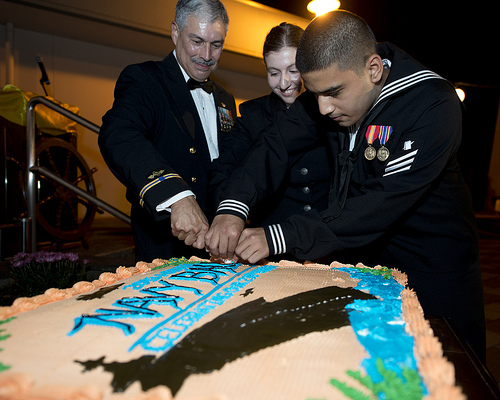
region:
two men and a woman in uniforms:
[98, 1, 488, 398]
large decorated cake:
[0, 251, 473, 398]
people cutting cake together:
[0, 1, 486, 398]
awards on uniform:
[362, 122, 392, 162]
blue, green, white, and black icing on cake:
[0, 255, 465, 398]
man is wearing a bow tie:
[96, 0, 241, 263]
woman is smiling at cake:
[205, 20, 336, 263]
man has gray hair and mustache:
[97, 0, 240, 272]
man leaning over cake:
[235, 8, 470, 398]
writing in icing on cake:
[65, 252, 281, 352]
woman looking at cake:
[240, 20, 310, 202]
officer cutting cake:
[103, 1, 237, 263]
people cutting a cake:
[214, 10, 465, 280]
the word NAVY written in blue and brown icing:
[57, 278, 202, 334]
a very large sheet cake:
[0, 251, 467, 397]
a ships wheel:
[11, 110, 106, 247]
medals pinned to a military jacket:
[361, 116, 396, 165]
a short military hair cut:
[291, 7, 378, 79]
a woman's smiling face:
[261, 17, 308, 109]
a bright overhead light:
[302, 1, 347, 18]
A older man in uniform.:
[97, 4, 238, 258]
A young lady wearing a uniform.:
[240, 13, 329, 256]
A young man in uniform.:
[295, 13, 477, 275]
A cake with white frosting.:
[2, 258, 432, 396]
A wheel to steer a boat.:
[12, 113, 109, 240]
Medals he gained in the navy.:
[363, 124, 391, 160]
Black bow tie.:
[184, 76, 219, 91]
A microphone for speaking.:
[28, 51, 65, 96]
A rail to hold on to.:
[23, 91, 128, 231]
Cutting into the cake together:
[157, 176, 299, 258]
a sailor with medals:
[295, 8, 470, 331]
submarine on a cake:
[72, 277, 382, 394]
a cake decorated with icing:
[4, 256, 499, 397]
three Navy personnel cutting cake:
[98, 2, 494, 252]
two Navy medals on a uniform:
[354, 120, 396, 170]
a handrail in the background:
[19, 92, 129, 259]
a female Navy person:
[222, 18, 307, 268]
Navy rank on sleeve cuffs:
[125, 160, 297, 263]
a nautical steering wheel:
[12, 127, 102, 247]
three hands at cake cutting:
[150, 189, 291, 267]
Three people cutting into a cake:
[93, 1, 477, 284]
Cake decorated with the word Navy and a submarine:
[0, 232, 461, 395]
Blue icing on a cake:
[346, 265, 409, 362]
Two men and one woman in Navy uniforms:
[96, 1, 481, 261]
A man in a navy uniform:
[300, 6, 468, 268]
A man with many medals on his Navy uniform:
[99, 2, 244, 251]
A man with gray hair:
[76, 0, 244, 272]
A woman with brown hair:
[231, 1, 306, 163]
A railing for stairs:
[3, 81, 130, 258]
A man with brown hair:
[298, 4, 473, 261]